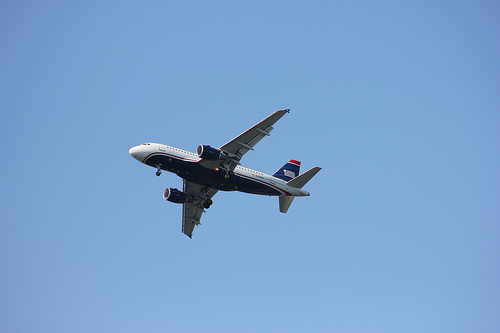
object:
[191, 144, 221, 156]
white line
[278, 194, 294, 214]
tail wing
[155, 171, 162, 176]
front wheel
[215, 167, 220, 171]
white light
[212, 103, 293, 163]
white wing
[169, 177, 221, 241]
white wing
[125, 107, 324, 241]
airplane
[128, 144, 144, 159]
nose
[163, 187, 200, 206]
engine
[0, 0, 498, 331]
clear sky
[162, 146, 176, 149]
window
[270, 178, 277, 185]
door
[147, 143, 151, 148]
window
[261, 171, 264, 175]
window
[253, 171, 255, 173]
window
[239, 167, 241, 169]
window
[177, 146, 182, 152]
window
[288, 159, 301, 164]
stripe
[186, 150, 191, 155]
window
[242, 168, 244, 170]
window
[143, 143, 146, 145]
window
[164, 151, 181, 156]
stripe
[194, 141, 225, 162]
engine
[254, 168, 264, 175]
window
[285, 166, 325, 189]
tail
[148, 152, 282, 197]
underbody